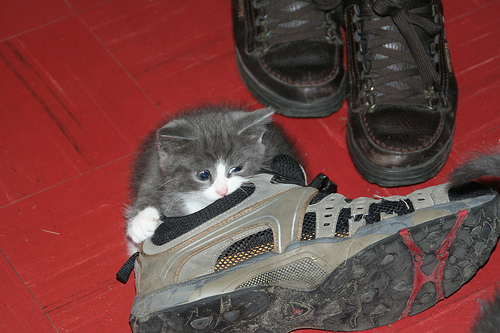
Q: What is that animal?
A: A kitten.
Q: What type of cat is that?
A: A grey-white tabby.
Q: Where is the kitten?
A: In the shoe.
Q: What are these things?
A: Shoes.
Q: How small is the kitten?
A: Enough to fit inside the shoe.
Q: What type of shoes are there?
A: Sneakers.